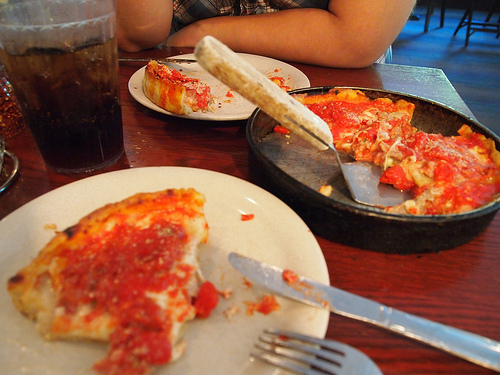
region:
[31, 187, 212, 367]
this is a pizza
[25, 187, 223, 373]
the pizza is sliced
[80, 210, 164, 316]
the pizza is red in color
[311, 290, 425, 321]
this is a knife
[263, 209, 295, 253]
this is a plate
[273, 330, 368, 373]
this is a fork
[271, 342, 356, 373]
the fork is metallic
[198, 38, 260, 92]
the handle is wooden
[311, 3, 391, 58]
this is a hand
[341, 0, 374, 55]
the hand is white in color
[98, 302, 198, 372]
This is a piece of pizza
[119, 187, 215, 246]
This is a piece of pizza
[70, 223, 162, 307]
This is a piece of pizza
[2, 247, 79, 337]
This is a piece of pizza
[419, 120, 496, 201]
This is a piece of pizza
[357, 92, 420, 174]
This is a piece of pizza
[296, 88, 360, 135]
This is a piece of pizza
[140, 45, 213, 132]
This is a piece of pizza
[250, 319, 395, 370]
This is a folk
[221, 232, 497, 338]
This is a knife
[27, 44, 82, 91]
the liquid is a brown black color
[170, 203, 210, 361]
the pizza has bites taken out of it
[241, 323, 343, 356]
the fork is silver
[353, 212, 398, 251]
the pan is black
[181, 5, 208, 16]
the shirt is plaid style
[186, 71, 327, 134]
the spachula handle is tan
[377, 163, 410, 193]
the sauce is red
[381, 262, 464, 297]
the table is a wood pattern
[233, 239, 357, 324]
the knife has sauce on it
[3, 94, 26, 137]
the container has red pepper seeds in it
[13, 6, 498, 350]
Eatable things on the wooden table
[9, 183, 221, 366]
Red and brown color of the bread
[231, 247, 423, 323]
A silver color metal knife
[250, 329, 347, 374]
A silver color metal fork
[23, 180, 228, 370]
A white color ceramic plate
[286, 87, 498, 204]
A black color frying pan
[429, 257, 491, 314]
Brownish color wooden table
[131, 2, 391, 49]
Hands of the person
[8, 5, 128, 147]
A glass with cool drinks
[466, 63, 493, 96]
Floor of the building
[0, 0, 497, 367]
A man eating pizza at a table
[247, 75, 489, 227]
Two slices of deep dish pizza in a tray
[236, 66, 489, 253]
A circular black tray under the pizza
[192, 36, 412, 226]
A metal spatula wedged into the pizza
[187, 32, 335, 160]
The wooden handle of a spatula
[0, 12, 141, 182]
Some sort of brown beverage in a cup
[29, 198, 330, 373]
A slice of pizza on a plate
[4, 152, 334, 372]
A white plate under the pizza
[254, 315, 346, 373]
The fork has four prongs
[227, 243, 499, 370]
A butter knife with food on it